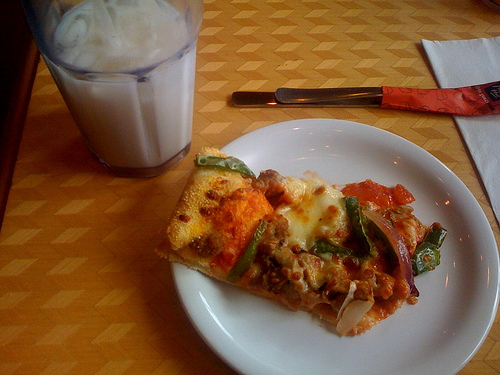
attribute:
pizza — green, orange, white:
[167, 144, 433, 315]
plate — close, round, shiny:
[171, 117, 494, 375]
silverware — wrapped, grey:
[228, 69, 496, 126]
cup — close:
[16, 4, 205, 175]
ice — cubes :
[55, 24, 164, 71]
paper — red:
[364, 57, 498, 124]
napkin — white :
[412, 33, 499, 240]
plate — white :
[161, 124, 462, 373]